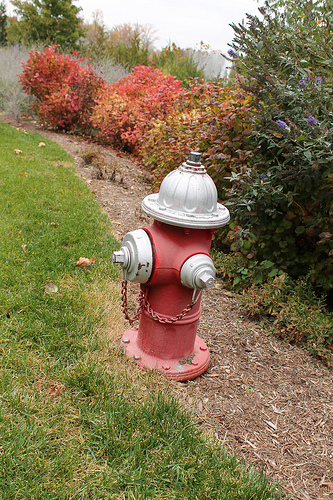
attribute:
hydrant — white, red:
[93, 125, 225, 395]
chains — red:
[117, 241, 200, 328]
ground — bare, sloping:
[26, 161, 313, 478]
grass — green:
[7, 177, 113, 319]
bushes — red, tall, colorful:
[57, 65, 265, 186]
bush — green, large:
[213, 35, 329, 310]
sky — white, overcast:
[95, 1, 240, 38]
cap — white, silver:
[137, 147, 229, 226]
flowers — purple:
[258, 52, 330, 171]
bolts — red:
[117, 321, 214, 366]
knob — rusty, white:
[111, 239, 154, 276]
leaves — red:
[19, 52, 74, 130]